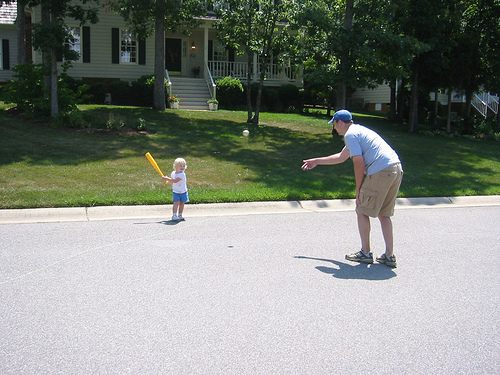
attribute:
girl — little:
[146, 149, 202, 224]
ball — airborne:
[226, 112, 262, 143]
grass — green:
[2, 96, 494, 206]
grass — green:
[10, 107, 498, 197]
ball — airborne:
[227, 102, 269, 157]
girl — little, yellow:
[162, 152, 191, 223]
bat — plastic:
[143, 147, 168, 181]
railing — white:
[208, 58, 298, 80]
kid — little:
[159, 153, 197, 223]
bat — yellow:
[140, 146, 170, 183]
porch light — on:
[188, 40, 198, 53]